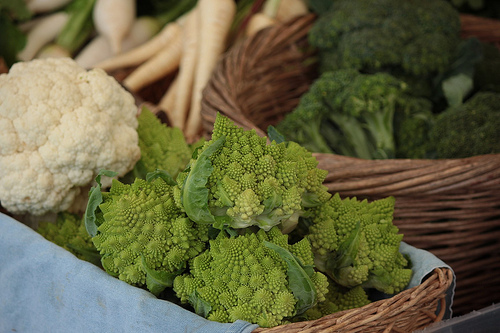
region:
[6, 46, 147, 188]
white food next to the green food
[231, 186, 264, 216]
one piece of green stuff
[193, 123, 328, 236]
green item stacked on other items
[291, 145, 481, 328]
two baskets next to each other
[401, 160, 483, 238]
brown basket in the photo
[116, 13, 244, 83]
food in the background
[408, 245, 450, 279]
blue cloth hanging out of basket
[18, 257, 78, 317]
side of the blue cloth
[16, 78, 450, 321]
many different items in photo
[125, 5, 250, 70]
blurry background of the photo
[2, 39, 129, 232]
head of fresh cauliflower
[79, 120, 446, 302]
fresh brussel sprouts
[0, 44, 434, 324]
basket of fresh vegetables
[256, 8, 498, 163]
several heads of fresh broccoli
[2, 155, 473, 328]
blue cloth in wicker basket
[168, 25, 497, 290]
broccoli in round basket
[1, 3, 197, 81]
fresh ears of corn in basket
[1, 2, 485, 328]
baskets of fresh vegetables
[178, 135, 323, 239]
delicate green leaf on brussel sprout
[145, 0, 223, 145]
several turnips in basket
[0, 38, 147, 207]
Cauliflowers in teh basket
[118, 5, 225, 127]
Rutabega in the basket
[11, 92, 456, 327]
A basket full of vegetables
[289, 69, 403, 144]
Broccoli in the basket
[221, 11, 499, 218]
The basket contains broccoli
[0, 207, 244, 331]
A cloth on the side of the basket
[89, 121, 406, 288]
The basket has green vegetables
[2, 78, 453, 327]
A basket holding food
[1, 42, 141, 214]
The cauliflowers is next to the green vegetables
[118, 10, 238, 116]
The rutabega is near the broccoli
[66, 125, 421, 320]
light green cruciferous vegetable cross between broccoli and cauliflower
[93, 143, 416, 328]
broccoflower in a basket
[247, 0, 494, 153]
heads of broccoli in a wicker basket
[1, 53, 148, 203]
a head of cauliflower in a basket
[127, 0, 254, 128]
a bunch of parsnips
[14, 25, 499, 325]
cruciferous vegetables cauliflower, broccoflower and broccoli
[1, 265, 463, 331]
wicker basket lined with a light blue cloth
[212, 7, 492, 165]
a large basket of broccoli heads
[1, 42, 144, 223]
perfectly formed snow white head of cauliflower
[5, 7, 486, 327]
several varieties of farm fresh garden vegetables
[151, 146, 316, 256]
green stuff in a basket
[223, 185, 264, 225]
part of the green stuff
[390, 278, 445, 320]
basket with stuff in it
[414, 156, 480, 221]
basket next to the green stuff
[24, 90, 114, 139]
white item next to green one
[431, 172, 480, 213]
brown basket next to other basket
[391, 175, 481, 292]
two different baskets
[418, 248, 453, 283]
cloth hanging out of the basket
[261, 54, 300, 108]
side of the basket